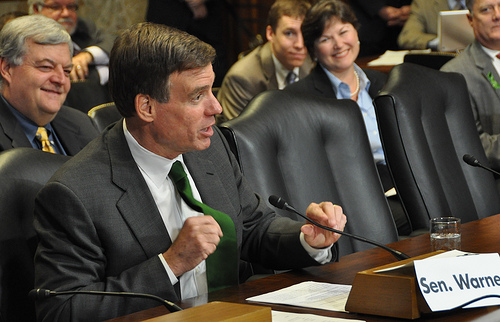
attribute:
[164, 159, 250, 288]
tie — green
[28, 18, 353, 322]
man — talking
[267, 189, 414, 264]
microphone — black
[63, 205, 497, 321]
table — brown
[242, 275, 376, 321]
paper — white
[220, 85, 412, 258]
chair — black, empty, leather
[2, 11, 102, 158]
man — old, sitting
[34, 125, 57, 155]
tie — yellow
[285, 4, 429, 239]
women — smiling, laughing, sitting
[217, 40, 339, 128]
suit jacket — grey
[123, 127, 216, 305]
shirt — white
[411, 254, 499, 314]
name tag — white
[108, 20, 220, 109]
hair — black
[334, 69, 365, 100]
pearls — white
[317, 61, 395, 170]
shirt — blue, open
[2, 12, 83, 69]
hair — grey